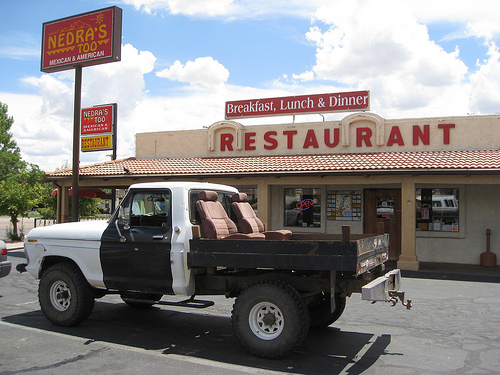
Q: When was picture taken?
A: Daytime.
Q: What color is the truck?
A: Black and white.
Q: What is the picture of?
A: Restaurant.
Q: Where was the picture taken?
A: At a restaurant.